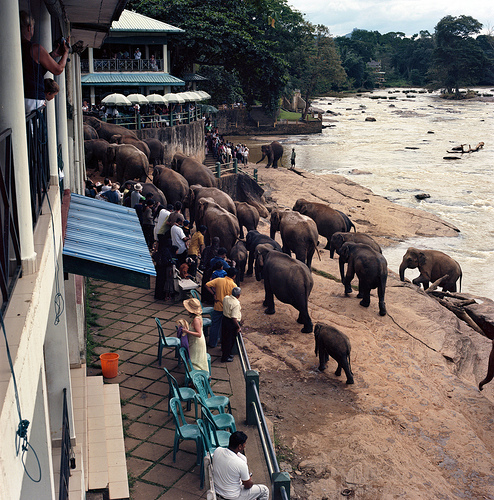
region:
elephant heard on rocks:
[73, 80, 491, 498]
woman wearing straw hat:
[179, 285, 202, 328]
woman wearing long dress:
[176, 298, 211, 381]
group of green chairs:
[153, 326, 248, 452]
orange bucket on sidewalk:
[80, 334, 130, 394]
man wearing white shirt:
[204, 439, 255, 491]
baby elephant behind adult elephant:
[244, 235, 363, 390]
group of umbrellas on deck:
[82, 72, 218, 155]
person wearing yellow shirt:
[202, 270, 237, 316]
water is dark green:
[252, 87, 483, 186]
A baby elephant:
[297, 317, 357, 386]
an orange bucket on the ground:
[91, 341, 129, 377]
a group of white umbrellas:
[99, 82, 211, 110]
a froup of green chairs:
[149, 364, 243, 450]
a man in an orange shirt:
[204, 265, 235, 312]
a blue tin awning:
[65, 190, 153, 285]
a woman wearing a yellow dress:
[169, 298, 216, 374]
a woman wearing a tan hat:
[173, 288, 211, 367]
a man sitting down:
[200, 425, 265, 497]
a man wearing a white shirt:
[196, 422, 276, 494]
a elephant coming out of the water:
[384, 219, 472, 307]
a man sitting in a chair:
[200, 428, 279, 495]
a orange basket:
[68, 329, 145, 398]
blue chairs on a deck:
[150, 325, 248, 467]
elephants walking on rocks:
[152, 161, 413, 400]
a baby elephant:
[280, 295, 378, 400]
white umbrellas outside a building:
[91, 66, 252, 119]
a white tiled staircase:
[47, 367, 156, 493]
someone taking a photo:
[12, 3, 87, 76]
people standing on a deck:
[104, 166, 257, 331]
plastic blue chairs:
[146, 318, 239, 447]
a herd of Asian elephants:
[83, 110, 492, 418]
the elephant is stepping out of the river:
[388, 218, 474, 332]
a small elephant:
[302, 309, 373, 404]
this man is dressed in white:
[208, 416, 257, 498]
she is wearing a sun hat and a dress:
[175, 287, 239, 399]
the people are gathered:
[88, 165, 251, 322]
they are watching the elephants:
[87, 167, 252, 346]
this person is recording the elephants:
[18, 6, 92, 119]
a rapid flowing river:
[349, 73, 492, 316]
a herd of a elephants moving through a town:
[78, 108, 464, 382]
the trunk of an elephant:
[395, 261, 410, 282]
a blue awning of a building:
[66, 187, 157, 291]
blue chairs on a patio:
[152, 324, 228, 444]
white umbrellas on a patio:
[104, 84, 217, 114]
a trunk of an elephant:
[335, 254, 349, 281]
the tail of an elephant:
[308, 233, 324, 265]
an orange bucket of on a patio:
[95, 348, 125, 381]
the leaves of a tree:
[200, 17, 241, 50]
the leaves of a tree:
[361, 36, 404, 59]